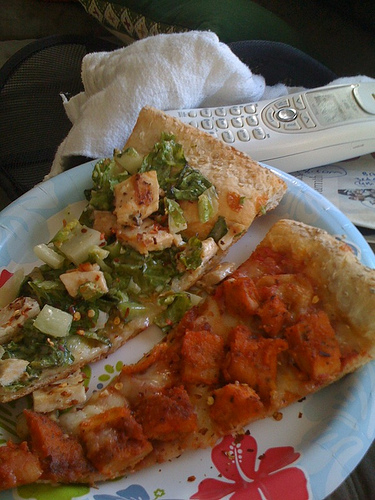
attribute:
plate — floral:
[3, 188, 204, 497]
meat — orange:
[147, 337, 273, 432]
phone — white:
[139, 71, 375, 173]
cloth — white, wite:
[78, 34, 234, 122]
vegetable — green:
[53, 233, 135, 287]